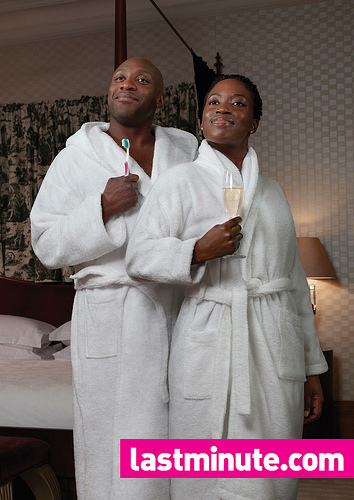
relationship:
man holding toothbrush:
[29, 56, 199, 500] [119, 135, 131, 175]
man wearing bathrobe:
[29, 56, 199, 500] [71, 135, 229, 470]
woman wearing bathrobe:
[124, 74, 328, 499] [87, 113, 349, 409]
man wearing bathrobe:
[29, 56, 199, 500] [29, 120, 197, 498]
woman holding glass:
[124, 74, 328, 499] [222, 169, 245, 258]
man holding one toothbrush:
[29, 56, 199, 500] [117, 136, 134, 172]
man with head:
[29, 56, 199, 500] [108, 55, 164, 121]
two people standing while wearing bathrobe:
[48, 50, 294, 292] [124, 140, 328, 500]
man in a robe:
[78, 52, 177, 173] [42, 152, 168, 497]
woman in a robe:
[124, 74, 328, 499] [121, 137, 328, 499]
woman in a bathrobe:
[124, 74, 328, 499] [124, 140, 328, 500]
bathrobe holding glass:
[124, 140, 328, 500] [220, 165, 246, 262]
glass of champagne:
[220, 165, 246, 262] [223, 181, 244, 222]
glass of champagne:
[220, 165, 246, 262] [223, 185, 243, 211]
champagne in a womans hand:
[223, 185, 243, 211] [190, 213, 243, 266]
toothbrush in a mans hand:
[121, 137, 133, 175] [100, 174, 140, 225]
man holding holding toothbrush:
[29, 56, 199, 500] [93, 123, 147, 213]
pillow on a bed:
[0, 310, 49, 349] [2, 269, 66, 444]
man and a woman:
[29, 56, 199, 500] [195, 73, 272, 171]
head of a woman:
[201, 71, 261, 143] [129, 74, 325, 437]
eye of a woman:
[172, 75, 278, 116] [157, 78, 329, 365]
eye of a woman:
[232, 100, 244, 107] [124, 74, 328, 499]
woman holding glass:
[124, 74, 328, 499] [221, 161, 258, 269]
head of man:
[100, 43, 167, 125] [29, 56, 199, 500]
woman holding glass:
[159, 53, 343, 381] [215, 168, 249, 264]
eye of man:
[111, 74, 126, 82] [108, 70, 127, 86]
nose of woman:
[213, 102, 235, 116] [211, 98, 248, 129]